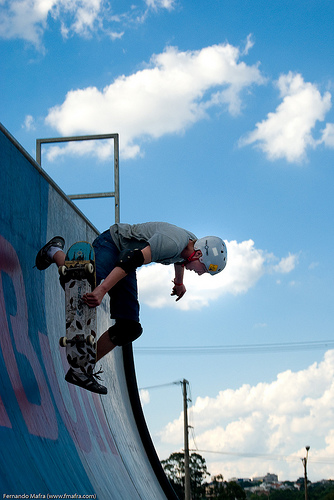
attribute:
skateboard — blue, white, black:
[58, 241, 98, 376]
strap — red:
[175, 249, 195, 261]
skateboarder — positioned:
[32, 219, 233, 417]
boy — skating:
[31, 194, 247, 408]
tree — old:
[156, 450, 210, 498]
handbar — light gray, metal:
[34, 130, 120, 231]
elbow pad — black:
[115, 239, 141, 269]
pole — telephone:
[40, 129, 154, 228]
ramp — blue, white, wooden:
[43, 347, 146, 434]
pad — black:
[108, 319, 143, 352]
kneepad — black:
[112, 321, 143, 349]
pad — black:
[114, 245, 148, 276]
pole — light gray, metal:
[171, 372, 202, 498]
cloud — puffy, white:
[233, 64, 331, 168]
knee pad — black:
[106, 317, 141, 347]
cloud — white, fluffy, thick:
[234, 74, 332, 168]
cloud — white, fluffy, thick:
[35, 33, 264, 166]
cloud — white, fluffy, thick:
[0, 3, 188, 76]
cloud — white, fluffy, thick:
[134, 235, 277, 310]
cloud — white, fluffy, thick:
[164, 347, 330, 493]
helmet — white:
[196, 233, 230, 280]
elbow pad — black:
[114, 247, 145, 274]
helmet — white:
[195, 234, 227, 275]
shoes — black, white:
[35, 238, 66, 270]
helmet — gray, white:
[192, 235, 229, 277]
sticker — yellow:
[207, 262, 219, 271]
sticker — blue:
[203, 238, 210, 255]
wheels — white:
[55, 330, 99, 348]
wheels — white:
[53, 255, 96, 277]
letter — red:
[2, 231, 71, 444]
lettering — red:
[0, 239, 119, 456]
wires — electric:
[135, 374, 190, 392]